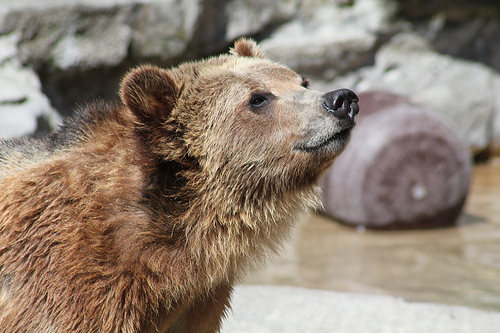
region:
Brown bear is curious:
[2, 66, 427, 328]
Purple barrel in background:
[328, 84, 480, 224]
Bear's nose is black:
[319, 76, 364, 126]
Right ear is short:
[123, 60, 180, 118]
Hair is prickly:
[12, 130, 249, 297]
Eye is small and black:
[240, 90, 280, 109]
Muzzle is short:
[285, 122, 357, 153]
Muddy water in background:
[306, 215, 496, 310]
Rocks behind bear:
[8, 3, 435, 63]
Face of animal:
[151, 47, 371, 182]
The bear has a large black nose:
[313, 78, 363, 134]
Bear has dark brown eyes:
[242, 75, 278, 115]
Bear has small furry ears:
[120, 55, 205, 147]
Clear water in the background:
[322, 207, 451, 332]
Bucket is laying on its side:
[340, 72, 498, 249]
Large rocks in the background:
[30, 13, 193, 98]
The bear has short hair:
[15, 154, 135, 257]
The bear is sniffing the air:
[146, 12, 423, 213]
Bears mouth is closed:
[300, 119, 359, 174]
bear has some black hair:
[5, 110, 131, 187]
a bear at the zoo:
[15, 45, 380, 329]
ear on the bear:
[113, 51, 173, 119]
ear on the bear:
[230, 29, 275, 70]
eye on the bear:
[245, 81, 277, 123]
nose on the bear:
[320, 83, 373, 150]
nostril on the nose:
[330, 86, 344, 112]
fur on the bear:
[48, 182, 125, 287]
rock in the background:
[378, 30, 489, 127]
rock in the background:
[7, 23, 56, 128]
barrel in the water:
[367, 84, 453, 226]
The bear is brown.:
[3, 41, 373, 328]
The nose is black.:
[303, 85, 373, 140]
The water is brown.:
[344, 237, 490, 286]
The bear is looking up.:
[203, 51, 372, 177]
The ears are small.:
[121, 62, 191, 129]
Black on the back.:
[31, 98, 128, 149]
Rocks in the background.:
[10, 9, 486, 137]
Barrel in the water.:
[327, 80, 478, 226]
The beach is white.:
[248, 290, 498, 330]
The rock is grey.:
[21, 10, 161, 70]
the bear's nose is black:
[318, 85, 361, 125]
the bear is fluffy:
[0, 32, 365, 329]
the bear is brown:
[0, 32, 370, 332]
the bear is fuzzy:
[0, 32, 360, 331]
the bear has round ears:
[119, 36, 270, 122]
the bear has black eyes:
[239, 74, 312, 119]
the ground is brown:
[158, 138, 498, 331]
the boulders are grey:
[1, 0, 498, 165]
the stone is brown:
[309, 73, 473, 239]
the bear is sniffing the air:
[0, 40, 360, 331]